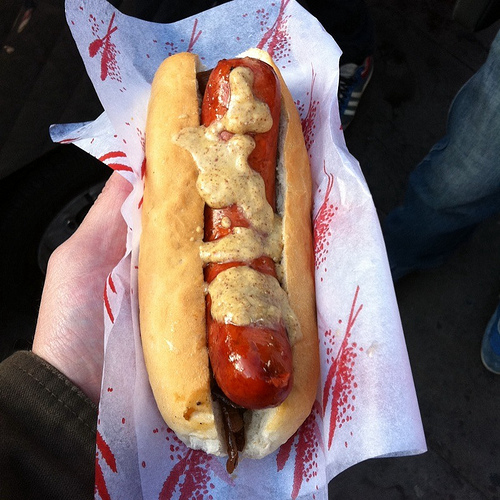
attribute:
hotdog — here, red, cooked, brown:
[202, 57, 293, 411]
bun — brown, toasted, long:
[136, 45, 319, 458]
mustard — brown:
[172, 67, 305, 343]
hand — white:
[30, 170, 133, 407]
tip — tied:
[263, 366, 294, 393]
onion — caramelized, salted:
[212, 390, 250, 472]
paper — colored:
[49, 0, 429, 499]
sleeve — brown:
[1, 347, 99, 499]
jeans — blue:
[381, 29, 500, 284]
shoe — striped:
[338, 62, 375, 129]